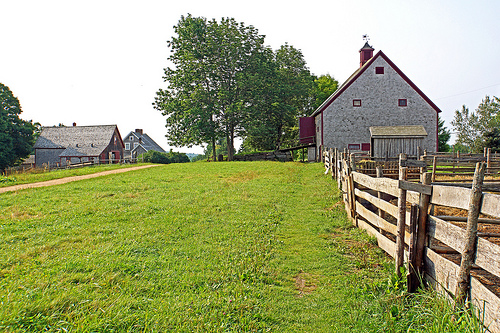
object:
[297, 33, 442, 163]
white house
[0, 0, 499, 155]
blue sky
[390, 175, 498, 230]
hay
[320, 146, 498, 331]
fence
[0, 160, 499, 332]
grass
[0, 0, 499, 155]
clouds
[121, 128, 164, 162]
house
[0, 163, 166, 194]
pathway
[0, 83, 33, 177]
tree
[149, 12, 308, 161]
trees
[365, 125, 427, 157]
shed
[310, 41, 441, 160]
barn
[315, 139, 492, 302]
fencing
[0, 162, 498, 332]
farm